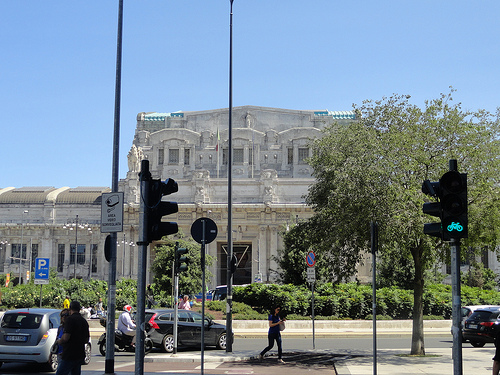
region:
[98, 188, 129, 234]
A rectangular white and black sign.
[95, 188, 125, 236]
A sign with a picture of a video camera.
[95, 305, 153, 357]
A man on a motorcycle.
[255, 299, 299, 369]
A woman in the middle of the picture.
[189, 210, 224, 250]
The back of a round sign.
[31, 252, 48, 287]
A blue and white rectangular sign.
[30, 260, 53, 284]
A white arrow pointing left.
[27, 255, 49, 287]
A sign indicating parking to the left.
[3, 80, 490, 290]
A large white building.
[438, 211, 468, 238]
A green neon bicycle on a light.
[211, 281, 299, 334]
this is a woman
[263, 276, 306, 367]
this is a bag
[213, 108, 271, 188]
this is a museum building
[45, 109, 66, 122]
there are no clouds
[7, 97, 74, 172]
the sky is very clear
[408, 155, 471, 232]
this is a street lamp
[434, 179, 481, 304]
the light is green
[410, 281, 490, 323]
this is a pole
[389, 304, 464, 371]
the pole is metal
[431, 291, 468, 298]
the pole is grey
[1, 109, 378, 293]
part of a white building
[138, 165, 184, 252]
a black street light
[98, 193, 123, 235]
a black and white sign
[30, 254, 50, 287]
a blue and white sign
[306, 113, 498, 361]
a large green tree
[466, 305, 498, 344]
part of a black vehicle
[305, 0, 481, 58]
part of a blue sky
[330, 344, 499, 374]
part of a sidewalk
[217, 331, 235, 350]
a tire of a vehicle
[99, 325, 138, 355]
part of a motorcycle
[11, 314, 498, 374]
Lady walking down street.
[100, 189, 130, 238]
White sign with picture of video camera.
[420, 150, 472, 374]
Traffic light on grey post.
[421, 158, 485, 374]
Traffic light with picture of green bike on it.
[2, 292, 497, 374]
Man wearing pink shirt crossing street.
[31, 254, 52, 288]
Blue parking sign with white directional arrow on it.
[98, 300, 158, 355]
Man riding black motorcycle.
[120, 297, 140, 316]
Red and grey motorcycle helmet.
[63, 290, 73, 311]
Person wearing short sleeved yellow shirt.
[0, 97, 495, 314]
Tall white building with many windows.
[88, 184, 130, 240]
a sign alerting people to video surveillance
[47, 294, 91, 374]
a couple talking next to the road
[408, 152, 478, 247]
a bicycle crossing sign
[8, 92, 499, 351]
a large grey stone building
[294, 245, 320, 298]
a no parking sign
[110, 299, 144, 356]
a motor cycle rider wearing a yellow and red helmet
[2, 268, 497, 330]
a row of bushes next to the road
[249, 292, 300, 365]
a lady walking in the shade of a tree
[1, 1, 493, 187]
a clear blue sky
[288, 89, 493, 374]
a healthy tree next to the road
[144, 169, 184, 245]
a black traffic light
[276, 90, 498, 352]
a large green tree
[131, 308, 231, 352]
the side of a black car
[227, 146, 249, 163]
a window of a building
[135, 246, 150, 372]
a tall gray pole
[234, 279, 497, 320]
a long row of green bushes